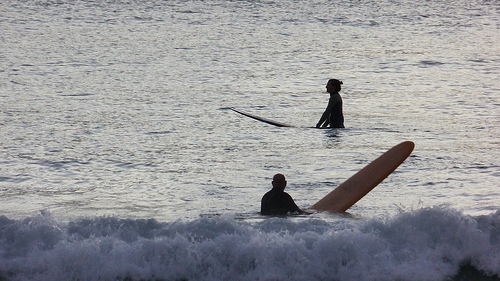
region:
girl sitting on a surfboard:
[309, 73, 366, 128]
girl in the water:
[301, 69, 391, 131]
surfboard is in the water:
[222, 87, 374, 136]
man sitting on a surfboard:
[241, 164, 344, 239]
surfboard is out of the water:
[303, 117, 440, 219]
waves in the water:
[33, 205, 454, 259]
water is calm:
[49, 35, 143, 113]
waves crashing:
[36, 232, 178, 269]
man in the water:
[229, 152, 324, 244]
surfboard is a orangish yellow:
[316, 131, 412, 194]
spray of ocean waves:
[7, 214, 499, 279]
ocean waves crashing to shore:
[3, 209, 497, 279]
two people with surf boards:
[215, 58, 430, 243]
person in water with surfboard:
[223, 68, 358, 139]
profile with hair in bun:
[322, 72, 347, 97]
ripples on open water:
[4, 3, 226, 216]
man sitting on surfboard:
[246, 135, 420, 235]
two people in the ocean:
[203, 67, 423, 237]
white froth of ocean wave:
[4, 207, 493, 276]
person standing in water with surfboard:
[215, 66, 362, 148]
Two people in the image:
[204, 60, 419, 232]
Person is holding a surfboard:
[248, 127, 423, 230]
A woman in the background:
[228, 64, 368, 140]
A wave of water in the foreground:
[4, 207, 495, 276]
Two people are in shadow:
[216, 63, 427, 219]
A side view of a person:
[303, 70, 360, 134]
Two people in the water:
[201, 70, 421, 216]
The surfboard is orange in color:
[312, 136, 429, 219]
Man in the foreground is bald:
[251, 167, 315, 225]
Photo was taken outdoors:
[4, 3, 496, 279]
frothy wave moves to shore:
[2, 208, 499, 280]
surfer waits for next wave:
[311, 52, 356, 145]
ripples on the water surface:
[0, 13, 240, 219]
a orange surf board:
[316, 133, 421, 218]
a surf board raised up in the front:
[302, 139, 430, 208]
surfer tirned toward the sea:
[251, 156, 317, 221]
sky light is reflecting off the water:
[213, 94, 300, 144]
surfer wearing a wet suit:
[256, 163, 311, 220]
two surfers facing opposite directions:
[213, 71, 422, 220]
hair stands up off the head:
[313, 67, 362, 130]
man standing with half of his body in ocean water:
[251, 167, 315, 232]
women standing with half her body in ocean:
[316, 64, 355, 148]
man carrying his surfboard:
[249, 135, 425, 225]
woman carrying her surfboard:
[217, 58, 361, 139]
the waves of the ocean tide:
[0, 195, 498, 279]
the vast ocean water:
[3, 4, 498, 74]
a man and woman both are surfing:
[191, 50, 423, 250]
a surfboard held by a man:
[304, 134, 430, 232]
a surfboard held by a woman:
[226, 68, 358, 144]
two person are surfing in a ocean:
[3, 1, 498, 279]